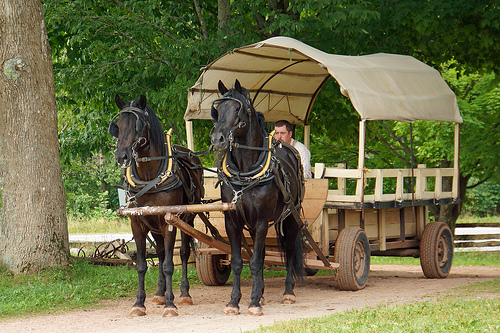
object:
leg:
[245, 217, 268, 319]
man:
[266, 117, 313, 184]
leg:
[281, 236, 297, 303]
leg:
[225, 228, 242, 315]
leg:
[130, 220, 150, 310]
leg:
[160, 227, 176, 309]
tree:
[1, 0, 76, 272]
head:
[209, 78, 253, 151]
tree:
[72, 8, 500, 124]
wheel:
[194, 244, 226, 287]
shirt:
[289, 137, 311, 178]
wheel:
[420, 220, 454, 278]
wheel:
[332, 221, 374, 292]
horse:
[110, 94, 202, 314]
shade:
[180, 38, 488, 147]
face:
[112, 109, 140, 165]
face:
[209, 92, 243, 149]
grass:
[284, 278, 500, 332]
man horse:
[347, 192, 417, 252]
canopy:
[181, 35, 463, 124]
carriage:
[184, 37, 464, 293]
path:
[6, 261, 497, 327]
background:
[0, 0, 499, 116]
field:
[0, 253, 500, 333]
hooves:
[247, 301, 266, 315]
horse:
[208, 78, 306, 313]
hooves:
[128, 303, 147, 317]